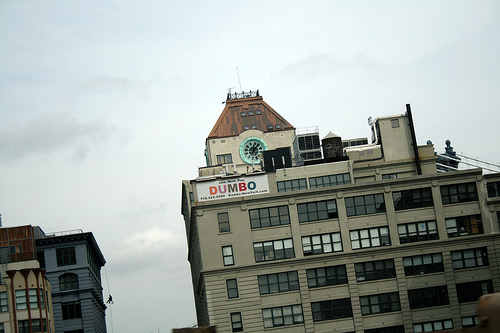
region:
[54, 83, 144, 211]
the sky is cloudy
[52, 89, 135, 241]
the sky is cloudy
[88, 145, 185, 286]
the sky is cloudy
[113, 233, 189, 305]
the sky is cloudy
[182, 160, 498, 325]
the building has windows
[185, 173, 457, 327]
the building has windows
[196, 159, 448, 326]
the building has windows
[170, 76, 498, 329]
this is a building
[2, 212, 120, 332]
this is a building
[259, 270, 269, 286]
this is a window pane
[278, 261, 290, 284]
this is a window pane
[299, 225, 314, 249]
this is a window pane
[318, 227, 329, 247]
this is a window pane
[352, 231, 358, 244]
this is a window pane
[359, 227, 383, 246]
this is a window pane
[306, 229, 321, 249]
this is a window pane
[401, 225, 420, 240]
this is a window pane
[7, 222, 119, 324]
this is a bulding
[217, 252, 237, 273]
this is a window pane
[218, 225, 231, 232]
this is a window pane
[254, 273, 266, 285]
this is a window pane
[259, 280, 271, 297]
this is a window pane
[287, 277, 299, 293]
this is a window pane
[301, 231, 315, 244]
this is a window pane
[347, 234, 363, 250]
this is a window pane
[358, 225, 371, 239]
this is a window pane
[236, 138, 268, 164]
Clock in tall tower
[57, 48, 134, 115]
Nice hazy blue sky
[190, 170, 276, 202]
Advertising sign for Dumbo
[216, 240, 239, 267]
Small window in large building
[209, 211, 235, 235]
Small window in large building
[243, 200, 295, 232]
Window in large building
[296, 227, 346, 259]
Window in large building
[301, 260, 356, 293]
Window in large building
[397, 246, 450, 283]
Window in large building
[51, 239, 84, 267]
Window in large building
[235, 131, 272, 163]
this is a clock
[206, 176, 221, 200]
the orange letter D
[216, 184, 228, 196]
the purple letter U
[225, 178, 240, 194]
the green letter M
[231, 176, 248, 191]
the red letter B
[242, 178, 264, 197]
the blue letter O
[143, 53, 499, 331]
a very large building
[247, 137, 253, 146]
the black number 12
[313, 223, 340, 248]
this is a window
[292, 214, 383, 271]
these are the windows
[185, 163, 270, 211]
dumbo banner on roof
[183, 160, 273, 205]
dumbo banner on roof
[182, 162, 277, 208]
dumbo banner on roof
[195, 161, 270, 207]
dumbo banner on roof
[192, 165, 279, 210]
dumbo banner on roof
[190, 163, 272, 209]
dumbo banner on roof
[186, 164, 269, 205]
dumbo banner on roof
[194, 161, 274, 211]
dumbo banner on roof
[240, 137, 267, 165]
window is round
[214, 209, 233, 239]
window on front of building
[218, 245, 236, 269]
window on front of building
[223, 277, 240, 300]
window on front of building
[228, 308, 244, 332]
window on front of building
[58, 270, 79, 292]
window on front of building